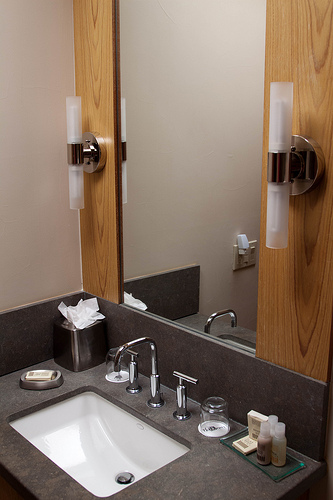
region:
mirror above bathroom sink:
[115, 8, 261, 342]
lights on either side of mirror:
[59, 79, 296, 247]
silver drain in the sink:
[113, 469, 131, 485]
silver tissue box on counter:
[55, 296, 108, 374]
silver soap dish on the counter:
[19, 370, 61, 388]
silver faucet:
[110, 341, 162, 404]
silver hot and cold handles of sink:
[119, 342, 194, 419]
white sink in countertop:
[8, 387, 191, 499]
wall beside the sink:
[2, 5, 77, 296]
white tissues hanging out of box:
[59, 297, 102, 326]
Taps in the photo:
[119, 348, 197, 408]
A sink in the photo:
[67, 394, 127, 468]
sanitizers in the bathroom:
[247, 426, 305, 477]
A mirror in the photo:
[160, 214, 228, 282]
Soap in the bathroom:
[18, 362, 61, 385]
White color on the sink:
[63, 406, 126, 454]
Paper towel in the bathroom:
[65, 294, 102, 323]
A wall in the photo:
[33, 234, 74, 300]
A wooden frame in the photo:
[269, 271, 311, 342]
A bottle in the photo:
[200, 391, 226, 439]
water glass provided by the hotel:
[197, 395, 231, 437]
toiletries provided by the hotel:
[233, 406, 288, 468]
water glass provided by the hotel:
[104, 345, 133, 384]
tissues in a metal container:
[49, 297, 114, 373]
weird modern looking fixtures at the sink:
[114, 328, 198, 424]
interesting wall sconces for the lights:
[260, 74, 296, 255]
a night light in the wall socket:
[233, 230, 250, 259]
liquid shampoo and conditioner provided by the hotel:
[254, 412, 287, 468]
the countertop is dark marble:
[0, 288, 322, 495]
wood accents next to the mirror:
[70, 1, 132, 309]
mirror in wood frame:
[72, 2, 331, 383]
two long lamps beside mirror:
[66, 83, 320, 250]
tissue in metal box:
[53, 297, 109, 373]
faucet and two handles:
[112, 336, 198, 420]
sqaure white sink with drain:
[7, 386, 194, 496]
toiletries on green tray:
[221, 408, 302, 482]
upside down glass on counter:
[199, 395, 228, 435]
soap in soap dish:
[20, 368, 61, 389]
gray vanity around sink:
[1, 348, 317, 497]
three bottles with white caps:
[258, 415, 286, 466]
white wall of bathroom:
[1, 0, 80, 310]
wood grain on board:
[255, 0, 332, 381]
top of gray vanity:
[1, 350, 322, 497]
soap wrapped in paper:
[24, 369, 56, 381]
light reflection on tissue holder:
[69, 328, 88, 373]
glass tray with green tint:
[220, 428, 303, 481]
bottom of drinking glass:
[197, 395, 230, 436]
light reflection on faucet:
[116, 335, 159, 407]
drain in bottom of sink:
[115, 471, 134, 484]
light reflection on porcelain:
[47, 419, 106, 464]